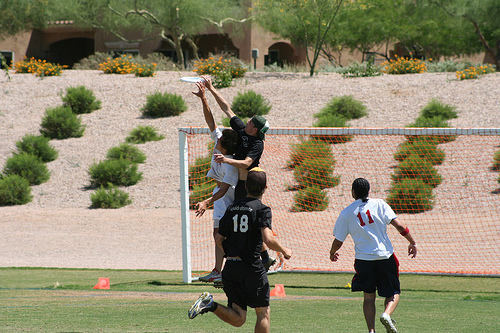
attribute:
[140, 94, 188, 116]
bush — green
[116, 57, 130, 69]
flowers — yellow, yellowy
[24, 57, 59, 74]
flowers — yellow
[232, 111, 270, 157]
man — jumping, playing, reachig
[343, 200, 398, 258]
shirt — white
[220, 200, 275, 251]
shirt — black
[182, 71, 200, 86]
frisbee — white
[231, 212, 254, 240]
number — 18, white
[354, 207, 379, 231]
number — 11, red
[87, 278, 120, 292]
cone — orange, orage, over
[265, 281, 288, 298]
cone — orange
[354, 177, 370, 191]
hair — black, cornrows, short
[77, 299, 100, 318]
grass — green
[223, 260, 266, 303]
shorts — black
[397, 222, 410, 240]
band — red